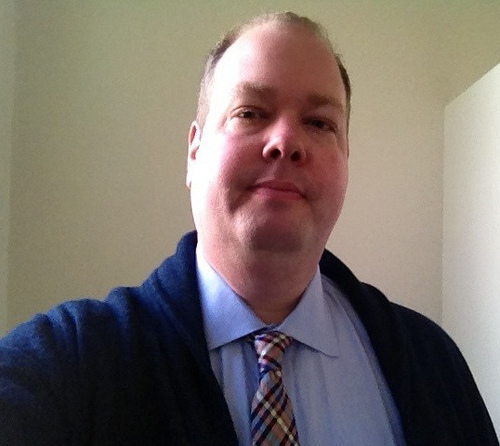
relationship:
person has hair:
[9, 7, 498, 444] [187, 4, 367, 166]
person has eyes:
[9, 7, 498, 444] [226, 100, 342, 135]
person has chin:
[9, 7, 498, 444] [225, 188, 317, 257]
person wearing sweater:
[9, 7, 498, 444] [5, 225, 496, 445]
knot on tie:
[253, 334, 291, 371] [247, 329, 303, 444]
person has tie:
[9, 7, 498, 444] [247, 329, 303, 444]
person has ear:
[9, 7, 498, 444] [178, 114, 204, 185]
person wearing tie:
[9, 7, 498, 444] [247, 329, 303, 444]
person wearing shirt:
[9, 7, 498, 444] [184, 245, 403, 444]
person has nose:
[9, 7, 498, 444] [260, 102, 309, 168]